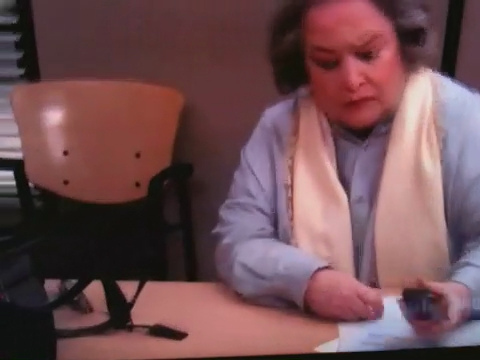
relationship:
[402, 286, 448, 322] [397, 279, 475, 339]
phone in hand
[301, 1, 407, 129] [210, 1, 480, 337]
head of woman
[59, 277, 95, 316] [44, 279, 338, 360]
glasses on table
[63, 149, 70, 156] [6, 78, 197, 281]
bolt in chair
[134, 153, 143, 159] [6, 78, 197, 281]
bolt in chair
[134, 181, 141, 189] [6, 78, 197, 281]
bolt in chair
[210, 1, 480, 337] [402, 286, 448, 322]
woman holding onto phone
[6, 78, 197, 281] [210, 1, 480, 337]
chair beside woman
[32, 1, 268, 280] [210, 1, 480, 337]
wall behind woman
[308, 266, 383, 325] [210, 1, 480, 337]
hand of woman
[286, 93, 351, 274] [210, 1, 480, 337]
scarf on woman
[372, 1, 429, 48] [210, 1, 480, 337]
hair of woman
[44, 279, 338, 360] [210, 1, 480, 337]
table in front of woman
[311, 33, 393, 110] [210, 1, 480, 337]
face of woman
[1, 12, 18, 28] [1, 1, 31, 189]
blinds at window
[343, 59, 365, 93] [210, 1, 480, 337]
nose of woman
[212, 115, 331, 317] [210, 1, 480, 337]
arm of woman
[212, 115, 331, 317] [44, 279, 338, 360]
arm on table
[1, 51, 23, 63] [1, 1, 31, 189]
blinds on window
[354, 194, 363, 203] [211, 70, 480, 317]
button on shirt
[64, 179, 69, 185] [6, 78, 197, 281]
bolt on chair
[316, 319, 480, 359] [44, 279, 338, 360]
paper on table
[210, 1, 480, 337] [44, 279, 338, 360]
woman sitting at table